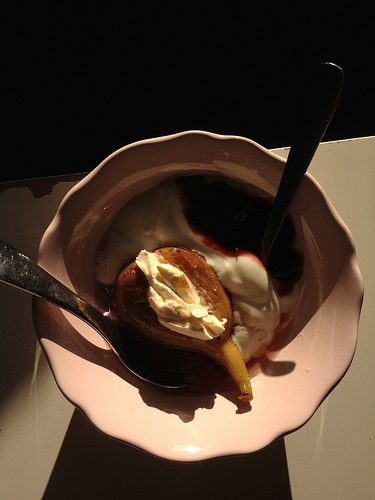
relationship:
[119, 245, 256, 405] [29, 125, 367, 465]
fig in bowl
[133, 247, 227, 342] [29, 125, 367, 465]
cream in bowl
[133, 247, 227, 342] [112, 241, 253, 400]
cream inside fig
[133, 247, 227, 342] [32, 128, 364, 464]
cream in a bowl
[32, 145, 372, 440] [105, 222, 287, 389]
bowl of food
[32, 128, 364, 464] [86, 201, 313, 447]
bowl of food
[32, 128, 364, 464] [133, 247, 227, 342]
bowl of cream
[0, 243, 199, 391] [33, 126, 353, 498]
spoon in a bowl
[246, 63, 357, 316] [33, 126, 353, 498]
spoon in a bowl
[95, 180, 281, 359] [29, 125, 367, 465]
fruit in bowl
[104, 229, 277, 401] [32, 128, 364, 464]
fruit in bowl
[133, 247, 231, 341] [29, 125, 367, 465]
cream in bowl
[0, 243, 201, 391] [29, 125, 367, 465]
spoon in bowl